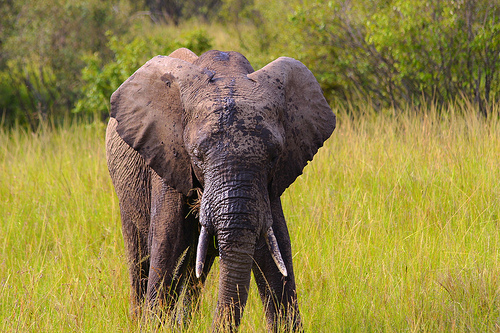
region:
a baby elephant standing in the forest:
[104, 41, 319, 332]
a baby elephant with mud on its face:
[189, 62, 291, 319]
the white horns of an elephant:
[257, 231, 297, 285]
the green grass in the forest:
[343, 167, 466, 299]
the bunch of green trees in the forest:
[322, 8, 491, 110]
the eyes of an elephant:
[182, 142, 214, 169]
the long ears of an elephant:
[85, 48, 208, 197]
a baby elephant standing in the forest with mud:
[11, 8, 433, 332]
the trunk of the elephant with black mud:
[215, 185, 263, 327]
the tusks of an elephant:
[194, 203, 298, 293]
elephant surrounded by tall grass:
[55, 26, 395, 317]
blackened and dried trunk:
[200, 160, 265, 220]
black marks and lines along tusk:
[260, 220, 290, 275]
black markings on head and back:
[205, 40, 255, 135]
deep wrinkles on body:
[100, 130, 150, 230]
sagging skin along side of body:
[105, 120, 150, 240]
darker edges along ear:
[111, 95, 186, 186]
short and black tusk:
[187, 206, 212, 281]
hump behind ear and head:
[160, 40, 197, 70]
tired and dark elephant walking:
[77, 37, 360, 322]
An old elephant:
[81, 47, 386, 319]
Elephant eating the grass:
[99, 86, 306, 293]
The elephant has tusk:
[186, 165, 333, 328]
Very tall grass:
[9, 130, 198, 327]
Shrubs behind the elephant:
[68, 26, 214, 56]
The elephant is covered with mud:
[81, 56, 353, 293]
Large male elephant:
[109, 31, 481, 243]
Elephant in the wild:
[101, 63, 221, 193]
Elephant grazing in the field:
[119, 66, 351, 315]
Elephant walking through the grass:
[94, 84, 345, 331]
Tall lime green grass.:
[338, 97, 496, 332]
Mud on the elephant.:
[191, 50, 311, 239]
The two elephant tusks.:
[194, 227, 289, 277]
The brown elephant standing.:
[103, 48, 335, 331]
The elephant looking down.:
[183, 53, 297, 191]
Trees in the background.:
[13, 2, 498, 44]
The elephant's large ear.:
[107, 54, 192, 191]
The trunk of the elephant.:
[200, 181, 270, 331]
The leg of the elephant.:
[138, 193, 188, 331]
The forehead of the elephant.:
[193, 77, 278, 127]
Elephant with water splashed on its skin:
[75, 33, 353, 328]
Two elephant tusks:
[175, 217, 310, 292]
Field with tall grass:
[1, 118, 498, 328]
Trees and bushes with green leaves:
[0, 3, 495, 133]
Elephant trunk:
[193, 172, 296, 329]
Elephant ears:
[93, 43, 343, 218]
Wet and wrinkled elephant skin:
[81, 97, 292, 258]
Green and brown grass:
[0, 109, 482, 327]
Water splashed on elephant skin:
[164, 42, 286, 287]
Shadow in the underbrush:
[0, 70, 104, 140]